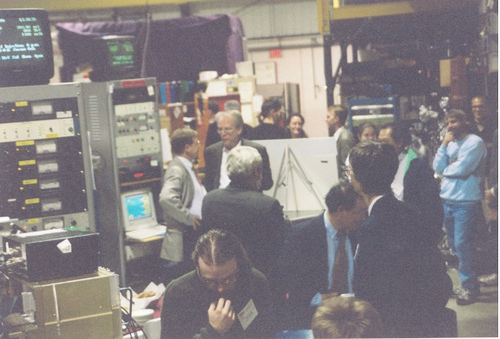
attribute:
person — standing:
[434, 108, 488, 305]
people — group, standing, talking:
[147, 96, 499, 337]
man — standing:
[161, 229, 275, 337]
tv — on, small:
[0, 9, 54, 86]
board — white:
[242, 138, 341, 221]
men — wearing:
[157, 93, 499, 338]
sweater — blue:
[434, 133, 488, 201]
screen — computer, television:
[97, 35, 138, 83]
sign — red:
[268, 47, 283, 60]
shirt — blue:
[325, 216, 356, 297]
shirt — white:
[175, 154, 210, 221]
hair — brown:
[351, 138, 400, 195]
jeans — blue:
[438, 200, 483, 291]